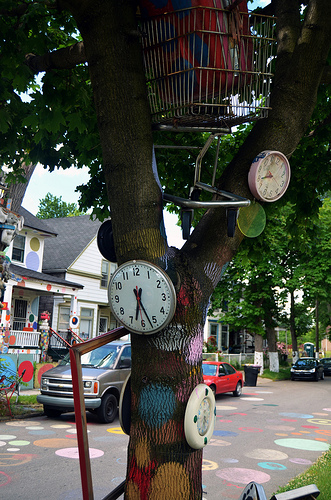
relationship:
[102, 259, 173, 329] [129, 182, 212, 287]
clock on tree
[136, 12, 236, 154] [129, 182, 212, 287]
basket in tree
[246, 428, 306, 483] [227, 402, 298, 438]
circles on street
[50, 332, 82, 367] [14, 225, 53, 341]
steps on house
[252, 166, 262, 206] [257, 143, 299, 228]
metal on clock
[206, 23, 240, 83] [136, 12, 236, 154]
red in basket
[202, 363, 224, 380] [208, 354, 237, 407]
windshield of car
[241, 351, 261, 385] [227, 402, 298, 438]
can by street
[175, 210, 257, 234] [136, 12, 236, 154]
wheels of basket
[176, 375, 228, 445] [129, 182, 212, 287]
clock on tree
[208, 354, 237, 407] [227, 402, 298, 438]
car on street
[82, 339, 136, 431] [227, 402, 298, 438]
van on street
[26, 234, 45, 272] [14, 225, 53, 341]
circles on house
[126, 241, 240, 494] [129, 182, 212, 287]
circles on tree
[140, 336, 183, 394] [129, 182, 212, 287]
trunk of tree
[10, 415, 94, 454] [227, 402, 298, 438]
paint on street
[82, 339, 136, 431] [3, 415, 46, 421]
van by curb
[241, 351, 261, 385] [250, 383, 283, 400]
can by road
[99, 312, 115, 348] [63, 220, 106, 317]
screendoor on house